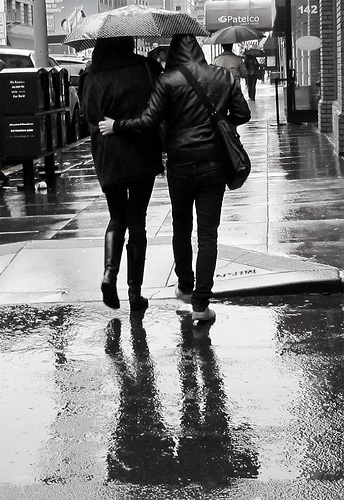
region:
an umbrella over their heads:
[56, 2, 215, 68]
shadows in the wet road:
[76, 274, 266, 493]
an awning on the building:
[201, 1, 285, 34]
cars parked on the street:
[2, 45, 98, 161]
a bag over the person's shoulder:
[158, 38, 254, 203]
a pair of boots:
[83, 214, 156, 321]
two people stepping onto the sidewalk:
[65, 234, 269, 333]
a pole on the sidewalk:
[30, 1, 56, 72]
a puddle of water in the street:
[5, 347, 63, 498]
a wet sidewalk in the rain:
[0, 84, 340, 309]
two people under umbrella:
[84, 22, 244, 315]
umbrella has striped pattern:
[78, 10, 217, 42]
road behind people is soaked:
[14, 301, 296, 470]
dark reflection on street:
[87, 317, 259, 485]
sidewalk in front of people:
[1, 241, 275, 281]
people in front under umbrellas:
[208, 28, 265, 90]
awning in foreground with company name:
[203, 4, 274, 33]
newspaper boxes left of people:
[7, 61, 80, 171]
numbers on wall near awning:
[297, 2, 327, 30]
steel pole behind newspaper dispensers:
[22, 12, 52, 72]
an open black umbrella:
[64, 7, 207, 47]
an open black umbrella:
[205, 22, 266, 51]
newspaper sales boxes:
[2, 66, 74, 187]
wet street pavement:
[1, 303, 343, 497]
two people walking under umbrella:
[65, 5, 249, 324]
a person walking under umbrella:
[207, 25, 266, 81]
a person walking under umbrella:
[240, 44, 264, 101]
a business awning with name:
[201, 0, 277, 31]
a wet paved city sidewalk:
[3, 72, 342, 300]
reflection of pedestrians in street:
[104, 311, 256, 498]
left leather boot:
[96, 229, 123, 316]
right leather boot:
[126, 238, 160, 318]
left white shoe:
[172, 278, 189, 308]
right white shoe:
[186, 301, 226, 324]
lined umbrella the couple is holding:
[61, 6, 193, 47]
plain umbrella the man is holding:
[210, 18, 262, 46]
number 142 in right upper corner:
[300, 2, 325, 17]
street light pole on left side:
[33, 1, 53, 71]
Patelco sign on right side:
[213, 11, 270, 33]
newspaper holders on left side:
[6, 70, 76, 149]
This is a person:
[154, 12, 273, 353]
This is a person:
[70, 16, 168, 338]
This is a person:
[240, 45, 272, 110]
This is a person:
[206, 21, 248, 124]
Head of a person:
[91, 22, 147, 64]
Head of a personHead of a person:
[162, 11, 211, 74]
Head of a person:
[217, 32, 237, 60]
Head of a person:
[245, 45, 259, 62]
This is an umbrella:
[62, 3, 224, 58]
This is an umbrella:
[203, 13, 261, 59]